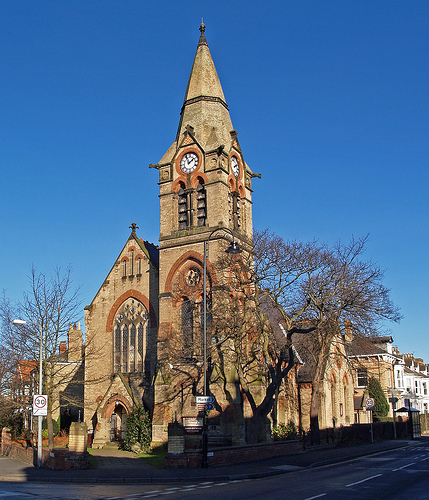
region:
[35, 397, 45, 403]
number 30 on a sign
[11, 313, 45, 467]
white street lamp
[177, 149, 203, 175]
round white clock face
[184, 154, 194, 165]
black hands on a clock face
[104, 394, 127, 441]
doorway at the entrance of a church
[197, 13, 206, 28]
steeple at the top of a tower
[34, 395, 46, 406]
red circle on a sign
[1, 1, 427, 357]
blue of daytime sky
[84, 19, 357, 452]
gothic style church with tower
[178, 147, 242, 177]
two clocks with white face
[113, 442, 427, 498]
white lines on street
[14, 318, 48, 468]
light and sign on pole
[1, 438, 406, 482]
sidewalk on corner of street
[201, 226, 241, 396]
light on curved pole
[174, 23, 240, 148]
steeple on top of tower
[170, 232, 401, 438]
tree with no leaves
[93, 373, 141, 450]
doorway on front of church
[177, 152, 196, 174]
Large clock on a building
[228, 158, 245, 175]
Large clock on a building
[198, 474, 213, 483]
White line on the pavement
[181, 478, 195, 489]
White line on the pavement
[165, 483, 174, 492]
White line on the pavement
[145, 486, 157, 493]
White line on the pavement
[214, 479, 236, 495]
White line on the pavement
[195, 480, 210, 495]
White line on the pavement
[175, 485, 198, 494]
White line on the pavement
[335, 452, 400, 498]
White line on the pavement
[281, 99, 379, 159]
the sky is clear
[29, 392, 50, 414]
a red and white sign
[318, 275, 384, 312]
the tree branches on the tree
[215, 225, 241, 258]
a streetlight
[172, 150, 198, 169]
a clock on the building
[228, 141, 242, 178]
clock on the side of the building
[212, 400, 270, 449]
a dark shadow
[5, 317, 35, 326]
a streetlight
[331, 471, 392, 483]
white line in the street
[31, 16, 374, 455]
a large stone church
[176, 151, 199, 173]
a black and white clock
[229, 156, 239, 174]
a black and white clock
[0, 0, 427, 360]
a clear blue sky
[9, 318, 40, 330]
an overhead street light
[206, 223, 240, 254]
an overhead street light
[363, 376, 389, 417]
a large trimmed bush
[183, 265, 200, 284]
a round stained glass window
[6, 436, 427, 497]
a paved city street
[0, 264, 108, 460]
a large bare leaved tree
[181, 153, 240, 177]
two clocks on the sides of a building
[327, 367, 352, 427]
two arches on the front of a building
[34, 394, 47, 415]
a black red and white sign on a pole